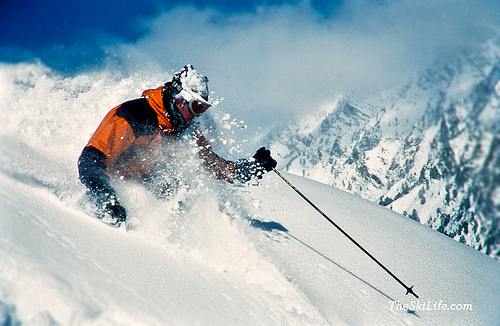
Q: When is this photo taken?
A: Daytime.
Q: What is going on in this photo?
A: Skiing.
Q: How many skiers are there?
A: One.